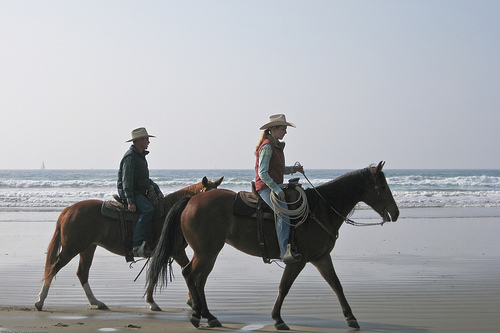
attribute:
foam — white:
[0, 174, 498, 212]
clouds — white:
[0, 0, 499, 169]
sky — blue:
[0, 0, 499, 170]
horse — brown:
[169, 147, 408, 317]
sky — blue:
[27, 43, 132, 120]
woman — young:
[254, 114, 304, 259]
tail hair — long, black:
[137, 195, 193, 305]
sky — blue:
[1, 1, 496, 108]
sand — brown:
[389, 235, 479, 325]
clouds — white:
[64, 20, 274, 97]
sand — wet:
[376, 251, 486, 300]